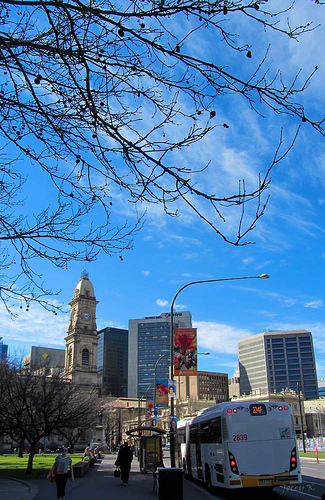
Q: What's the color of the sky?
A: Blue.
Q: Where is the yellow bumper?
A: On the white bus.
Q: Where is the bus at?
A: Bus stop.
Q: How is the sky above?
A: Cloudy.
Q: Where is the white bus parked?
A: On side of road.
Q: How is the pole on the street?
A: High.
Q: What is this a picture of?
A: Street.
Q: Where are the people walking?
A: Sidewalk.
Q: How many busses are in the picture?
A: One.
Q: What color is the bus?
A: White.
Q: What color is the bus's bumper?
A: Yellow.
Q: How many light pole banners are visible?
A: Three.